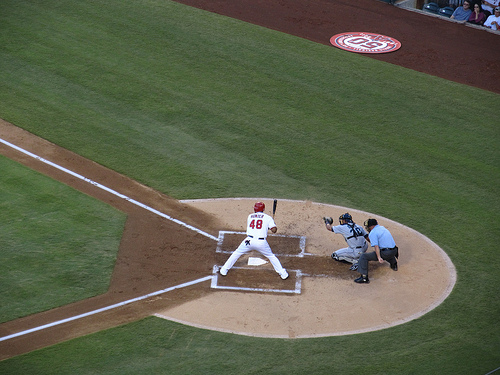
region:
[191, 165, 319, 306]
player in red and white uniform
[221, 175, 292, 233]
baseball player wearing red helmet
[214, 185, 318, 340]
baseball player ready to hit ball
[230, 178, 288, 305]
player with red number 48 on back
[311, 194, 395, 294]
catcher and umpire together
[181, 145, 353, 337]
baseball player at home plate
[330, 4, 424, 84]
red and white symbol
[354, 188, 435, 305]
umpire wearing blue short sleeved shirt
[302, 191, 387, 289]
catcher with hand up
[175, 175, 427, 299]
batter umpire catcher at home plate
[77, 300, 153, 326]
long white line on field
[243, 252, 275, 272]
white plate at home plate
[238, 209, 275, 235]
red number on back of jersey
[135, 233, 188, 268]
red dirt on the field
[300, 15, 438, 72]
large red and white circle on the field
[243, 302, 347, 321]
pink section of the home plate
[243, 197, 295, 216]
red helmet on man's head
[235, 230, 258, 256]
black glove in man's pocket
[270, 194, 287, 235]
black bat in man's hand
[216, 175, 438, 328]
people on the green field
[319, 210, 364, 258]
A catcher squatting low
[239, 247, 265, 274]
Home plate visible between a batter's legs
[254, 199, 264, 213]
A red batting helmet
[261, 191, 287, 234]
A bat held ready to hit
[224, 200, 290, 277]
A batter standing with legs apart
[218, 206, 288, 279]
A white with red baseball uniform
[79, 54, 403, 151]
Neatly mown grass on a baseball field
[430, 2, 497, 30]
Spectators in a dugout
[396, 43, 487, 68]
Dark dirt around the edge of the baseball field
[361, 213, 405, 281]
A referee standing behind the catcher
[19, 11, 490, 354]
a baseball field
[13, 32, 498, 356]
baseball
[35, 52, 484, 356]
a baseball game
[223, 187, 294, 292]
the batter is getting ready to hit a ball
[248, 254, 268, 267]
home plate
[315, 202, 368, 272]
the catcher kneels in the dirt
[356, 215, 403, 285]
the umpire crouches behind the catcher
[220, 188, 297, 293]
the player is wearing a white and red uniform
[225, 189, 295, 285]
the batter is wearing a red helmet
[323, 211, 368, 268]
the Catcher has a mask on his face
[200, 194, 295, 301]
baseball player up to bat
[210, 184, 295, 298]
baseball player at home plate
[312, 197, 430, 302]
catcher and umpire squatting down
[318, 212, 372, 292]
catcher ready to catch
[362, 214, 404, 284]
umpire squatting down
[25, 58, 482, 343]
baseball field at home plate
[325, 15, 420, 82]
circular logo with red and white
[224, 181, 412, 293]
three people playing baseball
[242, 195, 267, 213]
red helmet on player's head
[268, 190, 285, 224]
black baseball bat ready to swing